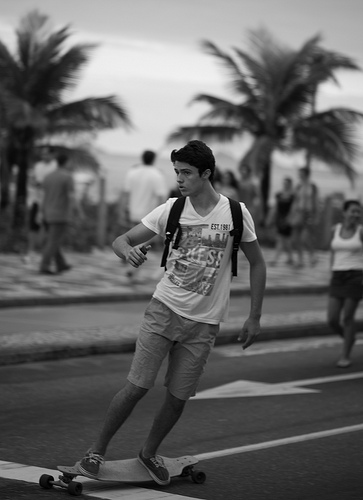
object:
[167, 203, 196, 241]
strap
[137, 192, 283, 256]
backpack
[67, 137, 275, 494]
boy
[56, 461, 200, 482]
skateboard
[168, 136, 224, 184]
hair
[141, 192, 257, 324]
shirt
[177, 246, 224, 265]
logo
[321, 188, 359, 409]
woman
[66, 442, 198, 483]
shoe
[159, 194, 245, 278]
straps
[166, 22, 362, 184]
palm tree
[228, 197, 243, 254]
strap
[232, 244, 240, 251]
buckle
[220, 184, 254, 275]
strap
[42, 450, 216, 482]
skateboard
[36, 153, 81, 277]
man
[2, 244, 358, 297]
sidewalk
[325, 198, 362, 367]
woman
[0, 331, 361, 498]
street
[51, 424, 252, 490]
skateboard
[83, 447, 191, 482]
skateboard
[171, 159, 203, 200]
facial expression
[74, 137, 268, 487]
kid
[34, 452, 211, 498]
skateboard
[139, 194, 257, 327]
shortsleeve shirt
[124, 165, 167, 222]
shortsleeve shirt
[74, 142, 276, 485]
man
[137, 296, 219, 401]
shorts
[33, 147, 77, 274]
man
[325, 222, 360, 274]
tank top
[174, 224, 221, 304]
design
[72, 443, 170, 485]
shoes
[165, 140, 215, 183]
hair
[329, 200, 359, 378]
woman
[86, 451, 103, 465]
laces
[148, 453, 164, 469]
laces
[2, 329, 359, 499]
plain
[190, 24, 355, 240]
tree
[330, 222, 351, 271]
shirt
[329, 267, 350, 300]
skirt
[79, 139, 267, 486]
male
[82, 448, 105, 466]
shoelace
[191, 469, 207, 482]
wheel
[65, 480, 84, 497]
wheel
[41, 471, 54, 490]
wheel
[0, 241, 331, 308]
sidewalk